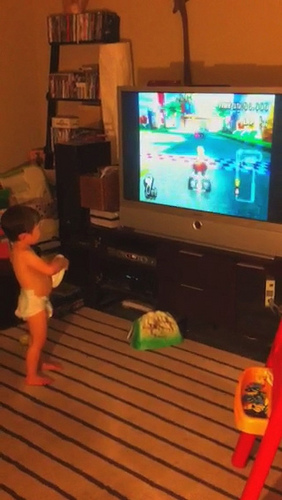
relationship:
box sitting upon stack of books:
[97, 162, 115, 197] [90, 205, 113, 234]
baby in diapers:
[0, 196, 67, 384] [15, 288, 56, 321]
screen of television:
[140, 90, 272, 221] [113, 84, 281, 259]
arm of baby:
[20, 249, 66, 276] [0, 196, 70, 388]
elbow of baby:
[38, 259, 53, 274] [0, 196, 70, 388]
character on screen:
[192, 144, 212, 198] [140, 90, 272, 221]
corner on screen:
[131, 91, 158, 116] [140, 90, 272, 221]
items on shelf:
[48, 68, 100, 95] [45, 90, 94, 106]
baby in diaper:
[0, 196, 70, 388] [13, 287, 55, 320]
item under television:
[123, 301, 185, 353] [113, 84, 281, 259]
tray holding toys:
[233, 362, 275, 441] [246, 375, 262, 422]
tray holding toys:
[233, 362, 275, 441] [245, 382, 266, 418]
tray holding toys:
[233, 362, 275, 441] [247, 378, 267, 421]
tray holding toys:
[235, 362, 279, 434] [246, 378, 271, 414]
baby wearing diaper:
[0, 196, 70, 388] [13, 287, 55, 320]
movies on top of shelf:
[46, 9, 121, 41] [50, 36, 131, 47]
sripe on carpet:
[1, 451, 78, 499] [0, 304, 273, 495]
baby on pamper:
[0, 196, 70, 388] [13, 289, 57, 325]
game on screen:
[128, 89, 276, 220] [110, 86, 280, 251]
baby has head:
[0, 196, 70, 388] [1, 204, 46, 246]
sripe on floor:
[1, 451, 78, 499] [4, 313, 236, 493]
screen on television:
[138, 90, 277, 222] [113, 84, 281, 259]